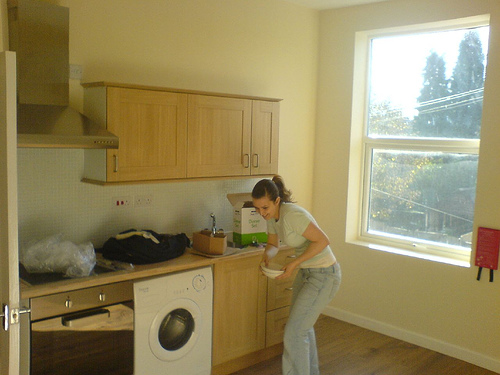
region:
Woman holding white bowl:
[247, 175, 343, 373]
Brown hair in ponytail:
[245, 168, 290, 213]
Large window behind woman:
[343, 13, 493, 265]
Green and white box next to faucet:
[222, 188, 267, 248]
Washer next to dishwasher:
[121, 265, 216, 373]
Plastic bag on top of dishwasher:
[18, 230, 98, 281]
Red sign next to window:
[467, 223, 499, 279]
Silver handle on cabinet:
[111, 152, 119, 172]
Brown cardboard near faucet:
[192, 227, 227, 255]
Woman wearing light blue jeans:
[245, 172, 344, 374]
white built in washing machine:
[132, 270, 215, 371]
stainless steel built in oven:
[33, 287, 135, 374]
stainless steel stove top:
[18, 260, 125, 280]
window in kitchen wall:
[363, 31, 488, 251]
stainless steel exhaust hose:
[7, 2, 113, 147]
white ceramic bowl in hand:
[262, 261, 282, 278]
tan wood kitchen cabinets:
[85, 82, 281, 175]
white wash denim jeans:
[281, 260, 339, 371]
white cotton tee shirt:
[266, 205, 333, 265]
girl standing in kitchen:
[253, 175, 341, 373]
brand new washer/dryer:
[132, 258, 217, 373]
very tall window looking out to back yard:
[340, 13, 489, 262]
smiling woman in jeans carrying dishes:
[250, 176, 338, 373]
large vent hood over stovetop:
[4, 2, 121, 164]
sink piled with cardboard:
[188, 209, 261, 257]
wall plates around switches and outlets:
[109, 191, 162, 213]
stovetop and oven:
[13, 238, 133, 373]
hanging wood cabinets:
[82, 82, 280, 183]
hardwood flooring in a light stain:
[223, 311, 492, 373]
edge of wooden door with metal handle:
[2, 48, 30, 373]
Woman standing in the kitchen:
[248, 175, 343, 371]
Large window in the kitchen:
[352, 21, 492, 261]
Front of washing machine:
[131, 267, 211, 372]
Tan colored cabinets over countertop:
[75, 77, 283, 184]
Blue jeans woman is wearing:
[278, 263, 338, 370]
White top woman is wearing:
[265, 200, 336, 270]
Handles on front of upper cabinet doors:
[240, 147, 263, 169]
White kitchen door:
[0, 47, 30, 372]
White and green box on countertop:
[225, 185, 270, 241]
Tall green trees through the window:
[413, 35, 489, 241]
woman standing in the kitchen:
[240, 173, 342, 373]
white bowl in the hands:
[255, 250, 299, 287]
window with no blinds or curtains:
[348, 21, 490, 276]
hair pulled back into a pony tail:
[241, 171, 298, 213]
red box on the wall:
[468, 224, 499, 269]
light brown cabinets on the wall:
[89, 81, 291, 186]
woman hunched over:
[237, 174, 354, 374]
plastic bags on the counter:
[16, 232, 103, 281]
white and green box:
[225, 186, 275, 246]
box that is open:
[223, 181, 271, 249]